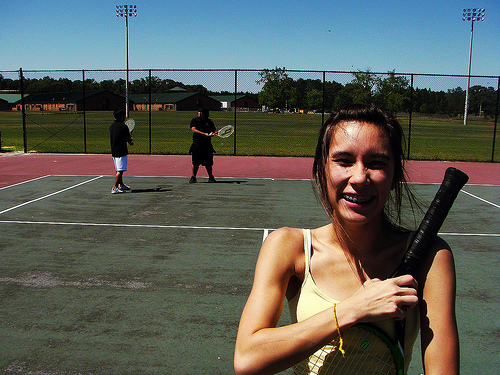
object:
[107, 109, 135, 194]
person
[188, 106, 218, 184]
person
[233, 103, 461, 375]
girl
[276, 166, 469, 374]
racket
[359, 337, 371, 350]
letter p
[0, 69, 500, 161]
chain linked fence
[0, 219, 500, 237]
white lines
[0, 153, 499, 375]
ground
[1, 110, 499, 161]
grass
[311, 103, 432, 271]
black hair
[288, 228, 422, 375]
tan shirt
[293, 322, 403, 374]
inside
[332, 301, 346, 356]
yellow bracelet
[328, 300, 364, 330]
wrist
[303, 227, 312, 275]
strap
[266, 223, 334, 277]
shoulder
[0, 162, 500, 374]
court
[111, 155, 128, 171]
white shorts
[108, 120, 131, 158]
black shirt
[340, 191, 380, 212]
smile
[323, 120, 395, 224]
face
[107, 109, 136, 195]
people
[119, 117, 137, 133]
rackets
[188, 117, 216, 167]
black clothing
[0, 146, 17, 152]
dough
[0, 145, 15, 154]
plate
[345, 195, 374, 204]
teeth